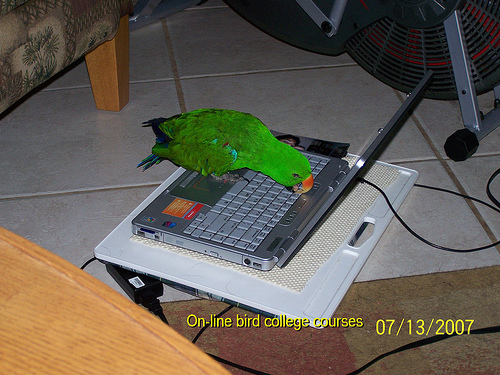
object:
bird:
[135, 107, 314, 195]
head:
[270, 135, 314, 196]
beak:
[284, 173, 315, 194]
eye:
[292, 173, 300, 178]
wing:
[149, 118, 239, 177]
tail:
[135, 114, 173, 174]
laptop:
[130, 67, 435, 273]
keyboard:
[181, 146, 331, 252]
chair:
[0, 0, 206, 123]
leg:
[83, 15, 131, 112]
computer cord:
[360, 176, 500, 254]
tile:
[161, 4, 360, 81]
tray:
[91, 129, 422, 332]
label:
[161, 196, 205, 220]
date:
[374, 318, 475, 338]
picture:
[0, 0, 500, 373]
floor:
[0, 0, 500, 374]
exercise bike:
[219, 0, 499, 165]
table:
[0, 223, 234, 375]